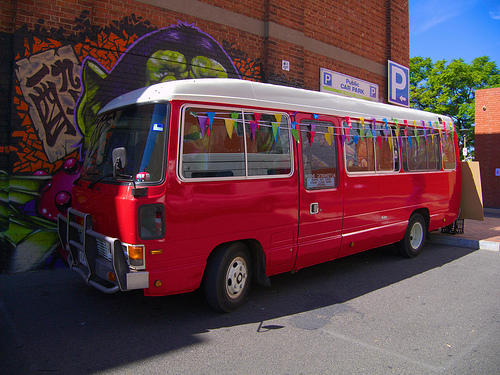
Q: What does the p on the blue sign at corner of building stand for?
A: Parking.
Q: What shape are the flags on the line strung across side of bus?
A: Triangle.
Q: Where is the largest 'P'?
A: On blue sign.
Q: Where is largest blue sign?
A: On the building.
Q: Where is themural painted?
A: On the building.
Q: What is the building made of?
A: Bricks.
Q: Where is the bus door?
A: On the side.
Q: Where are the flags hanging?
A: Side of the bus.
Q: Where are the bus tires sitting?
A: On the cement.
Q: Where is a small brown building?
A: Behind the bus.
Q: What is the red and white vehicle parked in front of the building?
A: Bus.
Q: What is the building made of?
A: Bricks.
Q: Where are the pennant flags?
A: Hanging on bus.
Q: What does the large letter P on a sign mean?
A: Parking.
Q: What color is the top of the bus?
A: White.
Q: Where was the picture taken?
A: Parking lot.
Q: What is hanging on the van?
A: Flags.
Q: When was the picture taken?
A: Daytime.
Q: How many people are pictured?
A: 0.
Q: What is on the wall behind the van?
A: Graffiti.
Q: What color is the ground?
A: Black.